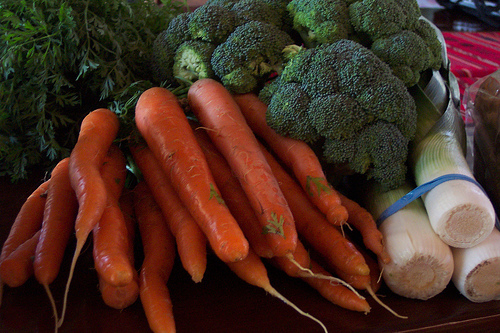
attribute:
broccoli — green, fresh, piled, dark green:
[150, 0, 445, 193]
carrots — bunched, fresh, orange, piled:
[2, 75, 407, 331]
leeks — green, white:
[355, 17, 500, 303]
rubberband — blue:
[375, 172, 499, 230]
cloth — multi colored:
[431, 30, 499, 126]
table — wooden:
[1, 2, 500, 331]